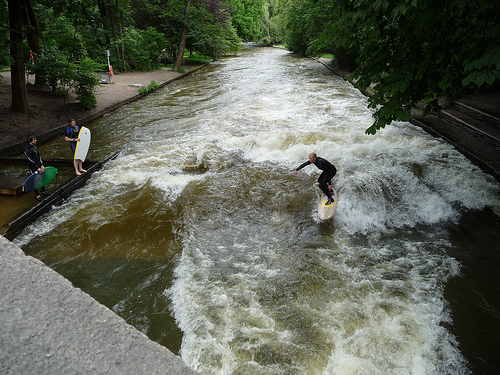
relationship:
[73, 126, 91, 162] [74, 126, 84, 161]
board has yellow edging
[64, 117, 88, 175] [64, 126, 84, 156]
person wearing a wetsuit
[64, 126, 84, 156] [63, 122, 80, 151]
wetsuit has black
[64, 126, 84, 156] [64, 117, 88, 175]
wetsuit worn by person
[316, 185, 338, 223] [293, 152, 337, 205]
surfboard under person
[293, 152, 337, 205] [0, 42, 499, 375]
person on water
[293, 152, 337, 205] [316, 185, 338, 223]
person on surfboard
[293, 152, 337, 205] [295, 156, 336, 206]
person wearing wetsuit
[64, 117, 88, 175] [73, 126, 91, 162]
person holding their board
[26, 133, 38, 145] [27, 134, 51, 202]
dark hair on person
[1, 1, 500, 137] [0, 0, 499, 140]
background has trees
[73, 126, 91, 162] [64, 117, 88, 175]
board carried by person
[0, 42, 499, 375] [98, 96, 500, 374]
water has waves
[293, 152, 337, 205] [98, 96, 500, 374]
person surfing waves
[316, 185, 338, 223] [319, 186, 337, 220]
surfboard colored grey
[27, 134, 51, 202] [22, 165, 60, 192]
person holding board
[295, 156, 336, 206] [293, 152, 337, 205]
wetsuit on person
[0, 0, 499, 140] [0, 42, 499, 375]
trees around water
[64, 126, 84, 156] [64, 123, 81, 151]
wetsuit has blue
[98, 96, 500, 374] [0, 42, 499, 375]
waves in water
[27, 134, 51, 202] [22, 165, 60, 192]
person holding their board